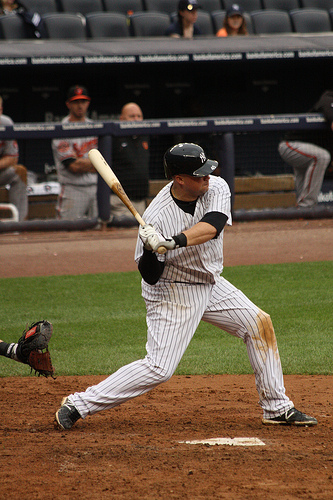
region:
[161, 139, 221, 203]
player's batting helmet is black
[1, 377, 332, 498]
home plate is in brown dirt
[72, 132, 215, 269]
the batter is batting right-handed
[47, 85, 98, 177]
the man's arms are folded in front of him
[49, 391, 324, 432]
the batter's sneakers are black with a white design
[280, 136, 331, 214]
a red stripe down gray pants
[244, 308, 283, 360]
dirt is on the batter's left knee pants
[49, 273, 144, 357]
green grass in the field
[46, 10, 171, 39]
empty chairs in the background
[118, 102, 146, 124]
the man has a bald head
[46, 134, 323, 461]
baseball player starting his swing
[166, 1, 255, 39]
two spectators watching baseball game from the first row behind 3rd base dugout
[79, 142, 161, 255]
wooden baseball bat with pine tar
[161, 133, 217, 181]
dark colored baseball batting helmet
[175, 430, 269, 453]
home plate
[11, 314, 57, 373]
catcher's mitt as player is ready to receive pitch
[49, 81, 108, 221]
baseball coach watching from dugout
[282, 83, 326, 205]
baseball player hanging on rail watching game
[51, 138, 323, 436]
baseball player wearing white and black pinstriped uniform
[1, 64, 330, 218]
third base side dugout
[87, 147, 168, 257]
a man holding a wooden baseball bat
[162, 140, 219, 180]
man wearing a black hard hat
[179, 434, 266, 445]
a white home plate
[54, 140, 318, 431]
baseball player about to hit a ball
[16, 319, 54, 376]
a black leather catcher's mitt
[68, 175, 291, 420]
man wearing a black and white stripe uniform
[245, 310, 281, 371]
dirt on man's pants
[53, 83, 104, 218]
a man crossing his arms on his chest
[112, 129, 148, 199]
man wearing a black shirt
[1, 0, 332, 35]
spectators in the bleachers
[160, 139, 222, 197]
the head of a man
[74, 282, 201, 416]
the leg of a man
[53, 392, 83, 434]
a black and white shoe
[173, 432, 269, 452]
a white home plate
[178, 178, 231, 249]
the arm of a man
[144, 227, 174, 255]
a white glove on the man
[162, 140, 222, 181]
a black helmet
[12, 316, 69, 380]
a black and brown catcher's mitt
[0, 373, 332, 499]
brown dirt on the ground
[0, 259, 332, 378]
a patch of green grass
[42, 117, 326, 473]
a batter in a baseball game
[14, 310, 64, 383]
a catcher's mitt in a baseball game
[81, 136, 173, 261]
a man holding a baseball bat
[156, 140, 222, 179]
a man wearing a baseball helmet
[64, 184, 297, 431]
a man wearing a baseball uniform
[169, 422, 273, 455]
home plate on a baseball field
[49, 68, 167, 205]
People in a dugout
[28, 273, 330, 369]
grass on a baseball field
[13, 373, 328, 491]
dirt on a baseball field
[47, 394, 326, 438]
cleats on a man's feet